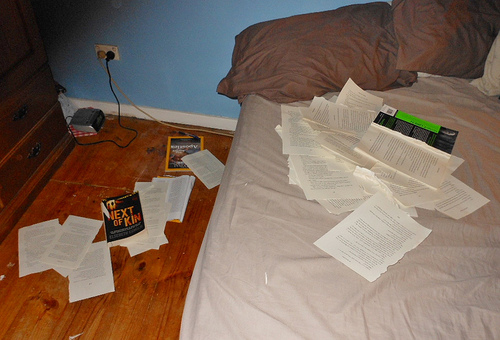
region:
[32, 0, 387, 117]
blue painted wall behind bed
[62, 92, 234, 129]
white molding on wall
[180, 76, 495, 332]
tan colored bed sheet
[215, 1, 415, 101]
dark brown pillow case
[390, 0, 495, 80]
dark brown pillow case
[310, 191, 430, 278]
white paper on bed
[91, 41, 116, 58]
white outlet on blue wall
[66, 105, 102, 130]
silver and black alarm clock on floor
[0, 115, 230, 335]
brown hard wood floor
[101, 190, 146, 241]
black book on wood floor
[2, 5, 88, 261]
a wooden dresser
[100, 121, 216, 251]
book on the floor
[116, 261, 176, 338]
hard wood floor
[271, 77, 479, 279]
torn pages on a bed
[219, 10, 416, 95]
a brown pillow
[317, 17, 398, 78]
wrinkles in a pillow cover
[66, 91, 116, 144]
an alarm clock on the floor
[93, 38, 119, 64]
a wall plug with a black and yellow plug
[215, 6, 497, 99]
three brown pillows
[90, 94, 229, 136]
white molding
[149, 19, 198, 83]
this is the wall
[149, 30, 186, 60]
the wall is blue in color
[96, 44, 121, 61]
this is the socket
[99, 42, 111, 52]
the socket is white in color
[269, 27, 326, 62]
this is a pillow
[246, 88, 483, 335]
this is the bed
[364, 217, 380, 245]
this is a paper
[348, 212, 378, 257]
the paper is white in color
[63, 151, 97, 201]
this is the floor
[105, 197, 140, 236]
this is a book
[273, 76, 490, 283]
A pile of scattered papers.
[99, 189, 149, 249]
A book titled "Next of Kin".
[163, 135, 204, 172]
A magazine with a yellow cover.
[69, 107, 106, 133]
A small silver alarm clock.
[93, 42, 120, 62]
A power socket in the wall.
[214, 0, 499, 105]
Two crumpled brown pillows.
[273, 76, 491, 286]
A book has been torn apart on the bed.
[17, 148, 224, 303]
Pages of the book are on the floor.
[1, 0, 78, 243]
A chest of drawers.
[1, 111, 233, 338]
The floor is made of wood.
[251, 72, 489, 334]
papers are on the bed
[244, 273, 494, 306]
the sheet is white in colour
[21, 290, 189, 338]
the floor is wooden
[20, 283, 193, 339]
its brown in colour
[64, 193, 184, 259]
a book is on the floor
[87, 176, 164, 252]
the cover is black in colour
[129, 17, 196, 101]
the wall is black in colour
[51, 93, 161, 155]
a radio is connected to the socket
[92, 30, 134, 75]
the socket is white in colour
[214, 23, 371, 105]
the pillow are brown in colour